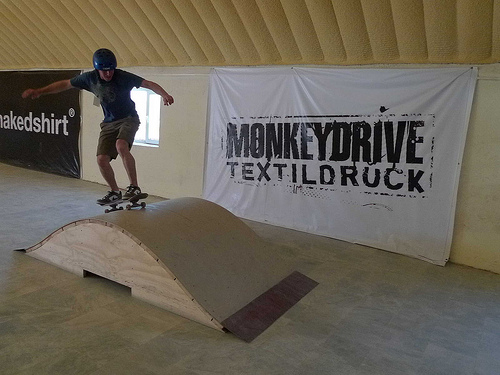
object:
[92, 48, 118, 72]
helmet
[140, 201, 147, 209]
wheels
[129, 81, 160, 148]
window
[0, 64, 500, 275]
wall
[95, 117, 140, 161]
brown pants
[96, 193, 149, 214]
skateboard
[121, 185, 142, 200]
feet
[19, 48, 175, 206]
man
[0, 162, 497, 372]
concrete floor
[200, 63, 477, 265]
sign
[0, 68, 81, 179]
signboard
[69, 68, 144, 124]
t-shirt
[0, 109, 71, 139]
lettering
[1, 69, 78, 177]
sign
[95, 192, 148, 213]
black skateboard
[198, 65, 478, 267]
signboard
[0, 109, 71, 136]
letters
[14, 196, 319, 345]
ramp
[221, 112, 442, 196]
writing